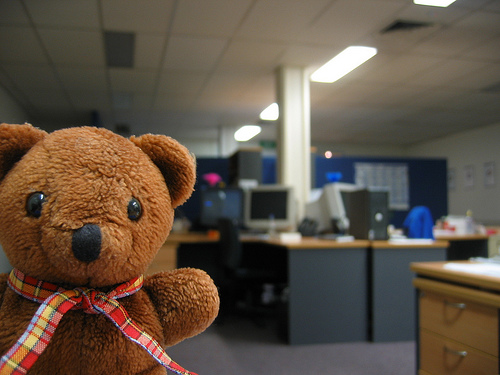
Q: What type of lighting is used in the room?
A: Fluorescent lights.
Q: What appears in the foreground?
A: A teddy bear.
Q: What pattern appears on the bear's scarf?
A: Plaid.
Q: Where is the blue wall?
A: Nearly all the way to the back wall on the right hand side.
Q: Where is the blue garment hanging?
A: Over the back of the chair in front of the blue wall.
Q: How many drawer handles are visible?
A: Two.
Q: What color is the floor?
A: Grey.